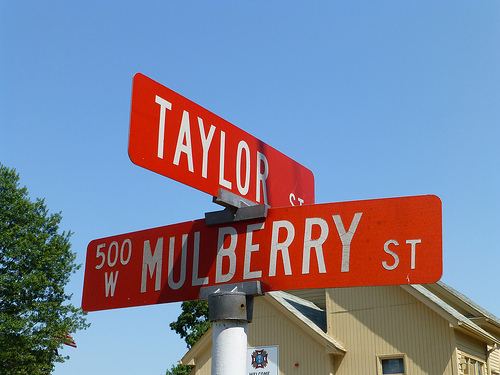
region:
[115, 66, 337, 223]
this is a sign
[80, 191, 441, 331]
this is a sign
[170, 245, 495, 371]
this is a house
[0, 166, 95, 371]
this is a tree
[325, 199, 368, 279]
a letter on the sign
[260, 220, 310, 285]
a letter on the sign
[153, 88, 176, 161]
a letter on the sign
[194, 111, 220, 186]
a letter on the sign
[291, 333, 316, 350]
the view of a white wall and chairs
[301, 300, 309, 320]
the view of a white wall and chairs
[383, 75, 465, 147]
a clear sky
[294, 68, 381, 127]
the sky is blue and clear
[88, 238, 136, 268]
numbers on the sign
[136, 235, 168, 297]
white letter M on red sign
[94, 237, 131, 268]
the number 500 on a street sign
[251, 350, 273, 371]
fire department logo on building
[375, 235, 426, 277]
the abbreviation for the word street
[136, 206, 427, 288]
street sign for Mulberry St.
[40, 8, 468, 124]
The sky is blue.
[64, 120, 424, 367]
Two signs on the pole.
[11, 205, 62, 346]
The tree is green.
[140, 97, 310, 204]
The top red sign says Taylor St.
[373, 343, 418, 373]
A window on the building.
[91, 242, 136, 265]
The number 500 on the sign.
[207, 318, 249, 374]
The pole is white.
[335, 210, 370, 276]
letter on a sign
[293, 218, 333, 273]
letter on a sign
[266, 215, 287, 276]
letter on a sign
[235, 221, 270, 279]
letter on a sign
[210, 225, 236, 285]
letter on a sign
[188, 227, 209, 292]
letter on a sign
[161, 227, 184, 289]
letter on a sign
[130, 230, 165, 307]
letter on a sign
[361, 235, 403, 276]
letter on a sign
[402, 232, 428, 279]
letter on a sign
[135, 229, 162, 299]
a letter on a sign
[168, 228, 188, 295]
a letter on a sign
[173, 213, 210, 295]
a letter on a sign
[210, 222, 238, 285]
a letter on a sign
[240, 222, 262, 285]
a letter on a sign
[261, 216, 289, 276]
a letter on a sign